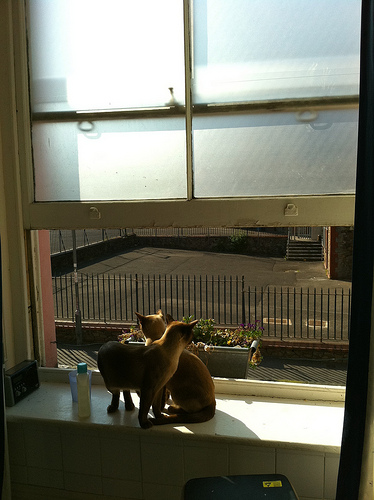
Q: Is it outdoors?
A: Yes, it is outdoors.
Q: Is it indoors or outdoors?
A: It is outdoors.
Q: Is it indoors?
A: No, it is outdoors.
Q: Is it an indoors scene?
A: No, it is outdoors.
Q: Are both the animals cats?
A: Yes, all the animals are cats.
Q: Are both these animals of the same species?
A: Yes, all the animals are cats.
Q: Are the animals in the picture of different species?
A: No, all the animals are cats.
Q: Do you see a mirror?
A: No, there are no mirrors.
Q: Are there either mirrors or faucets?
A: No, there are no mirrors or faucets.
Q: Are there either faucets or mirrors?
A: No, there are no mirrors or faucets.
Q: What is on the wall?
A: The tiles are on the wall.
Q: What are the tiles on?
A: The tiles are on the wall.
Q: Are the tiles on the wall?
A: Yes, the tiles are on the wall.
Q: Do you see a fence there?
A: Yes, there is a fence.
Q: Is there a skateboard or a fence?
A: Yes, there is a fence.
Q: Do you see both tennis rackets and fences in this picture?
A: No, there is a fence but no rackets.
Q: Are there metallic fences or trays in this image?
A: Yes, there is a metal fence.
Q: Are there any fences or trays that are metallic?
A: Yes, the fence is metallic.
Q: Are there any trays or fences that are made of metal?
A: Yes, the fence is made of metal.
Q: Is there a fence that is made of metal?
A: Yes, there is a fence that is made of metal.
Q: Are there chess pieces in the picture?
A: No, there are no chess pieces.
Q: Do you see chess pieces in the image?
A: No, there are no chess pieces.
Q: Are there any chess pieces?
A: No, there are no chess pieces.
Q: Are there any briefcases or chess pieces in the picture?
A: No, there are no chess pieces or briefcases.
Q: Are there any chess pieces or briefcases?
A: No, there are no chess pieces or briefcases.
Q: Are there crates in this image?
A: No, there are no crates.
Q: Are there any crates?
A: No, there are no crates.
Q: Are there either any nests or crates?
A: No, there are no crates or nests.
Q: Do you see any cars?
A: No, there are no cars.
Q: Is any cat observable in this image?
A: Yes, there is a cat.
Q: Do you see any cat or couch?
A: Yes, there is a cat.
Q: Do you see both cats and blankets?
A: No, there is a cat but no blankets.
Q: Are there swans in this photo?
A: No, there are no swans.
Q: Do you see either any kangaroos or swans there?
A: No, there are no swans or kangaroos.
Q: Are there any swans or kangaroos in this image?
A: No, there are no swans or kangaroos.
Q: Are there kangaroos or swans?
A: No, there are no swans or kangaroos.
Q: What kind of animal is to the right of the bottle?
A: The animal is a cat.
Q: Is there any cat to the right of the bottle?
A: Yes, there is a cat to the right of the bottle.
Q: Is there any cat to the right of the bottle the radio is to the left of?
A: Yes, there is a cat to the right of the bottle.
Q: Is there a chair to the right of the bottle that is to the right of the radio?
A: No, there is a cat to the right of the bottle.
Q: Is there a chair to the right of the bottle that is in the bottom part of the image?
A: No, there is a cat to the right of the bottle.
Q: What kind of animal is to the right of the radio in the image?
A: The animal is a cat.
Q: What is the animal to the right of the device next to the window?
A: The animal is a cat.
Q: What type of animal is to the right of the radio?
A: The animal is a cat.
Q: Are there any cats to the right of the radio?
A: Yes, there is a cat to the right of the radio.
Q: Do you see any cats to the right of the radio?
A: Yes, there is a cat to the right of the radio.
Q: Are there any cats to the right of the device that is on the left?
A: Yes, there is a cat to the right of the radio.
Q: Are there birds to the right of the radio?
A: No, there is a cat to the right of the radio.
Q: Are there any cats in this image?
A: Yes, there is a cat.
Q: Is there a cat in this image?
A: Yes, there is a cat.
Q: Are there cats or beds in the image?
A: Yes, there is a cat.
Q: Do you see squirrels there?
A: No, there are no squirrels.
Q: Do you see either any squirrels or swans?
A: No, there are no squirrels or swans.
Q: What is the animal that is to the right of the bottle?
A: The animal is a cat.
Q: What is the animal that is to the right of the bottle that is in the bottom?
A: The animal is a cat.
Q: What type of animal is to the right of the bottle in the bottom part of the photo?
A: The animal is a cat.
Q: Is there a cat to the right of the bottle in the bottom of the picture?
A: Yes, there is a cat to the right of the bottle.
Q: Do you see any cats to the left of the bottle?
A: No, the cat is to the right of the bottle.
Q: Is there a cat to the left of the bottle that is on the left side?
A: No, the cat is to the right of the bottle.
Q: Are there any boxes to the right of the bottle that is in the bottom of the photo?
A: No, there is a cat to the right of the bottle.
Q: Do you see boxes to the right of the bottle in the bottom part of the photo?
A: No, there is a cat to the right of the bottle.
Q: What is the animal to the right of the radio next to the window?
A: The animal is a cat.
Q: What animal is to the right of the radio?
A: The animal is a cat.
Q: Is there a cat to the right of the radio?
A: Yes, there is a cat to the right of the radio.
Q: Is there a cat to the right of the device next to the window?
A: Yes, there is a cat to the right of the radio.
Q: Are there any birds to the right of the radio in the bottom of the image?
A: No, there is a cat to the right of the radio.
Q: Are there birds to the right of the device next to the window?
A: No, there is a cat to the right of the radio.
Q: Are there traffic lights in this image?
A: No, there are no traffic lights.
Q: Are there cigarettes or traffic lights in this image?
A: No, there are no traffic lights or cigarettes.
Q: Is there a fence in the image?
A: Yes, there is a fence.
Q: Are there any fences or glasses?
A: Yes, there is a fence.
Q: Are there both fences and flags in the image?
A: No, there is a fence but no flags.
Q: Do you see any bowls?
A: No, there are no bowls.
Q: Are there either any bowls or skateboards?
A: No, there are no bowls or skateboards.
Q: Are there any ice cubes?
A: No, there are no ice cubes.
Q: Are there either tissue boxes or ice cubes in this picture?
A: No, there are no ice cubes or tissue boxes.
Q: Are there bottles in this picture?
A: Yes, there is a bottle.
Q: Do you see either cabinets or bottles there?
A: Yes, there is a bottle.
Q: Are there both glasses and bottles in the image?
A: Yes, there are both a bottle and glasses.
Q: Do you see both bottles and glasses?
A: Yes, there are both a bottle and glasses.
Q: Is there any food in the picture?
A: No, there is no food.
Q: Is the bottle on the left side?
A: Yes, the bottle is on the left of the image.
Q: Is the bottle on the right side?
A: No, the bottle is on the left of the image.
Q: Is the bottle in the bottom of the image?
A: Yes, the bottle is in the bottom of the image.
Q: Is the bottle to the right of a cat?
A: No, the bottle is to the left of a cat.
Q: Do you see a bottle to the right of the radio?
A: Yes, there is a bottle to the right of the radio.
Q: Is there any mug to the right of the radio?
A: No, there is a bottle to the right of the radio.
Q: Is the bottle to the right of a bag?
A: No, the bottle is to the right of the radio.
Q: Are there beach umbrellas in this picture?
A: No, there are no beach umbrellas.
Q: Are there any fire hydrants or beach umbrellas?
A: No, there are no beach umbrellas or fire hydrants.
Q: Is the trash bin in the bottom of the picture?
A: Yes, the trash bin is in the bottom of the image.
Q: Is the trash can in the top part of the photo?
A: No, the trash can is in the bottom of the image.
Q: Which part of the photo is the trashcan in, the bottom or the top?
A: The trashcan is in the bottom of the image.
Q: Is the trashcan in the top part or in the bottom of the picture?
A: The trashcan is in the bottom of the image.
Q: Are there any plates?
A: No, there are no plates.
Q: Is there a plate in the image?
A: No, there are no plates.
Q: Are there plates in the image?
A: No, there are no plates.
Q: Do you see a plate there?
A: No, there are no plates.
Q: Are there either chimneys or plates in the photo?
A: No, there are no plates or chimneys.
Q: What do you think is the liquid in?
A: The liquid is in the glass.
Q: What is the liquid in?
A: The liquid is in the glass.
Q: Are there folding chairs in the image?
A: No, there are no folding chairs.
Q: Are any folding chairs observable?
A: No, there are no folding chairs.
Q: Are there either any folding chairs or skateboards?
A: No, there are no folding chairs or skateboards.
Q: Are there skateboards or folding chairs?
A: No, there are no folding chairs or skateboards.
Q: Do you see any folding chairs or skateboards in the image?
A: No, there are no folding chairs or skateboards.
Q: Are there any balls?
A: No, there are no balls.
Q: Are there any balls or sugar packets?
A: No, there are no balls or sugar packets.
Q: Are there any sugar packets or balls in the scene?
A: No, there are no balls or sugar packets.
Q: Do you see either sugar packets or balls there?
A: No, there are no balls or sugar packets.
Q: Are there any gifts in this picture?
A: No, there are no gifts.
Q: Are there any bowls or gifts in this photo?
A: No, there are no gifts or bowls.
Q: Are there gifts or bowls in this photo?
A: No, there are no gifts or bowls.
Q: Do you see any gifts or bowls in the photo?
A: No, there are no gifts or bowls.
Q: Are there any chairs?
A: No, there are no chairs.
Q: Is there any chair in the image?
A: No, there are no chairs.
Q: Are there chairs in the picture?
A: No, there are no chairs.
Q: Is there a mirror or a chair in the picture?
A: No, there are no chairs or mirrors.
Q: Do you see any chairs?
A: No, there are no chairs.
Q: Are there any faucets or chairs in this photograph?
A: No, there are no chairs or faucets.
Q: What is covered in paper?
A: The glass is covered in paper.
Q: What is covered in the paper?
A: The glass is covered in paper.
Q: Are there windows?
A: Yes, there is a window.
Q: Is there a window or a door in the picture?
A: Yes, there is a window.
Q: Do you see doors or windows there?
A: Yes, there is a window.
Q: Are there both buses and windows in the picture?
A: No, there is a window but no buses.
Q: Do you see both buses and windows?
A: No, there is a window but no buses.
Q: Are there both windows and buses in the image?
A: No, there is a window but no buses.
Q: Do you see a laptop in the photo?
A: No, there are no laptops.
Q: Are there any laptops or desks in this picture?
A: No, there are no laptops or desks.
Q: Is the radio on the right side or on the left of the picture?
A: The radio is on the left of the image.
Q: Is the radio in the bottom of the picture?
A: Yes, the radio is in the bottom of the image.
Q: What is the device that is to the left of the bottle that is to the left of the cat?
A: The device is a radio.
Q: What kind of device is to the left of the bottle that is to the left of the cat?
A: The device is a radio.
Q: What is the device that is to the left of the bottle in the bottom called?
A: The device is a radio.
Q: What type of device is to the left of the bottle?
A: The device is a radio.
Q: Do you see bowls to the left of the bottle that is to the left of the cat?
A: No, there is a radio to the left of the bottle.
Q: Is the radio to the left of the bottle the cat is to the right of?
A: Yes, the radio is to the left of the bottle.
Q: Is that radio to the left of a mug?
A: No, the radio is to the left of the bottle.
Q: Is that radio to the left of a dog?
A: No, the radio is to the left of a cat.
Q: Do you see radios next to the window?
A: Yes, there is a radio next to the window.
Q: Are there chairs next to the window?
A: No, there is a radio next to the window.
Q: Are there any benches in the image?
A: No, there are no benches.